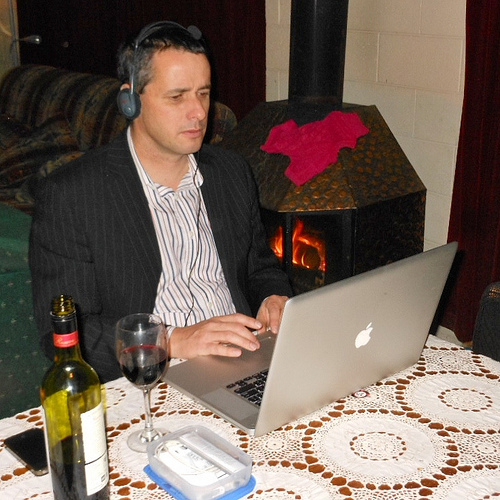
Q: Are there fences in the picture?
A: No, there are no fences.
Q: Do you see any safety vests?
A: No, there are no safety vests.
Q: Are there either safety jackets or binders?
A: No, there are no safety jackets or binders.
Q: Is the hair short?
A: Yes, the hair is short.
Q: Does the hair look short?
A: Yes, the hair is short.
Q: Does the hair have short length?
A: Yes, the hair is short.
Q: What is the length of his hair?
A: The hair is short.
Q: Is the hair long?
A: No, the hair is short.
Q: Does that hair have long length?
A: No, the hair is short.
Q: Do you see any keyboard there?
A: Yes, there is a keyboard.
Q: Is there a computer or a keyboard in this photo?
A: Yes, there is a keyboard.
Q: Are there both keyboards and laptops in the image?
A: Yes, there are both a keyboard and a laptop.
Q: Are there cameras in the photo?
A: No, there are no cameras.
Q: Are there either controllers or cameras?
A: No, there are no cameras or controllers.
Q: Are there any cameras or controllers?
A: No, there are no cameras or controllers.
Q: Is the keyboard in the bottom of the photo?
A: Yes, the keyboard is in the bottom of the image.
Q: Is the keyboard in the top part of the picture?
A: No, the keyboard is in the bottom of the image.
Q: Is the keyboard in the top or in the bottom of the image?
A: The keyboard is in the bottom of the image.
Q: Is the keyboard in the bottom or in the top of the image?
A: The keyboard is in the bottom of the image.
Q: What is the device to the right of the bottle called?
A: The device is a keyboard.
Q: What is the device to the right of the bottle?
A: The device is a keyboard.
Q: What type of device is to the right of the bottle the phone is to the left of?
A: The device is a keyboard.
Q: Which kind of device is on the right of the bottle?
A: The device is a keyboard.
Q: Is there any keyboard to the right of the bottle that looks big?
A: Yes, there is a keyboard to the right of the bottle.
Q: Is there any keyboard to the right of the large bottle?
A: Yes, there is a keyboard to the right of the bottle.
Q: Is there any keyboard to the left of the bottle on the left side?
A: No, the keyboard is to the right of the bottle.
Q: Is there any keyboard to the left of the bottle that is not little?
A: No, the keyboard is to the right of the bottle.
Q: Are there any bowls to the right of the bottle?
A: No, there is a keyboard to the right of the bottle.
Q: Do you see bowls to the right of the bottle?
A: No, there is a keyboard to the right of the bottle.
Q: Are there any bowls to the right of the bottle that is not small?
A: No, there is a keyboard to the right of the bottle.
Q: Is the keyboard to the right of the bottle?
A: Yes, the keyboard is to the right of the bottle.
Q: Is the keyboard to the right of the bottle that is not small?
A: Yes, the keyboard is to the right of the bottle.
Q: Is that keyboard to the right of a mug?
A: No, the keyboard is to the right of the bottle.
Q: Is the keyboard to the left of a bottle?
A: No, the keyboard is to the right of a bottle.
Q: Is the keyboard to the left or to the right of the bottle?
A: The keyboard is to the right of the bottle.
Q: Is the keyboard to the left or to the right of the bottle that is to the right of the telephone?
A: The keyboard is to the right of the bottle.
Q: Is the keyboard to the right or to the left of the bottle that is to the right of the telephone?
A: The keyboard is to the right of the bottle.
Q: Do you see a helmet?
A: No, there are no helmets.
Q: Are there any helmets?
A: No, there are no helmets.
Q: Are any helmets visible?
A: No, there are no helmets.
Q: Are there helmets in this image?
A: No, there are no helmets.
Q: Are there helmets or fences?
A: No, there are no helmets or fences.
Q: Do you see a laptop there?
A: Yes, there is a laptop.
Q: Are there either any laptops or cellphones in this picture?
A: Yes, there is a laptop.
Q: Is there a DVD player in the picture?
A: No, there are no DVD players.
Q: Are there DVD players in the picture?
A: No, there are no DVD players.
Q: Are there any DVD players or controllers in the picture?
A: No, there are no DVD players or controllers.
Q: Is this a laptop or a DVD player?
A: This is a laptop.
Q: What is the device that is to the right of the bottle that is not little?
A: The device is a laptop.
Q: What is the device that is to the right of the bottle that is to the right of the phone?
A: The device is a laptop.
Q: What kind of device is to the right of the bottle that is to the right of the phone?
A: The device is a laptop.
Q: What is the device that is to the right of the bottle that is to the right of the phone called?
A: The device is a laptop.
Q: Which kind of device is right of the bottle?
A: The device is a laptop.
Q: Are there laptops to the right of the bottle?
A: Yes, there is a laptop to the right of the bottle.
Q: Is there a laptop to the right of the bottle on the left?
A: Yes, there is a laptop to the right of the bottle.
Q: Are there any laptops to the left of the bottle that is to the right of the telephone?
A: No, the laptop is to the right of the bottle.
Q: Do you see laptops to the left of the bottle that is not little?
A: No, the laptop is to the right of the bottle.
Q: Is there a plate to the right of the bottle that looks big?
A: No, there is a laptop to the right of the bottle.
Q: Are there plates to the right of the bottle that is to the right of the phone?
A: No, there is a laptop to the right of the bottle.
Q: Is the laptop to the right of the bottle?
A: Yes, the laptop is to the right of the bottle.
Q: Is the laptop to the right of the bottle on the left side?
A: Yes, the laptop is to the right of the bottle.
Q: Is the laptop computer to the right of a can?
A: No, the laptop computer is to the right of the bottle.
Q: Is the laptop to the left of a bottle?
A: No, the laptop is to the right of a bottle.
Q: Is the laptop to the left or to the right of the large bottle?
A: The laptop is to the right of the bottle.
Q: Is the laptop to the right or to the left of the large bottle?
A: The laptop is to the right of the bottle.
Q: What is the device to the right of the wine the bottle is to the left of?
A: The device is a laptop.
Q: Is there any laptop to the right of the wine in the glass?
A: Yes, there is a laptop to the right of the wine.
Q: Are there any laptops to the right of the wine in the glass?
A: Yes, there is a laptop to the right of the wine.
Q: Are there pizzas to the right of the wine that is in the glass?
A: No, there is a laptop to the right of the wine.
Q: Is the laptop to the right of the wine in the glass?
A: Yes, the laptop is to the right of the wine.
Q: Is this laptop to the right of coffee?
A: No, the laptop is to the right of the wine.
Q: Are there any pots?
A: No, there are no pots.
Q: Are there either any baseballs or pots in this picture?
A: No, there are no pots or baseballs.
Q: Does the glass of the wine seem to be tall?
A: Yes, the glass is tall.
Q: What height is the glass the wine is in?
A: The glass is tall.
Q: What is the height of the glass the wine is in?
A: The glass is tall.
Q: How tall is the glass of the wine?
A: The glass is tall.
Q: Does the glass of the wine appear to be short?
A: No, the glass is tall.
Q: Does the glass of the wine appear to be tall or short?
A: The glass is tall.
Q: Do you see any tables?
A: Yes, there is a table.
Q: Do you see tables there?
A: Yes, there is a table.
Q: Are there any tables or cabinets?
A: Yes, there is a table.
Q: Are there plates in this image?
A: No, there are no plates.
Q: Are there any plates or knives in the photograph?
A: No, there are no plates or knives.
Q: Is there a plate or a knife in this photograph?
A: No, there are no plates or knives.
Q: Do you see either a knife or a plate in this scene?
A: No, there are no plates or knives.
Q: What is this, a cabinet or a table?
A: This is a table.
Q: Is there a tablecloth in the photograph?
A: Yes, there is a tablecloth.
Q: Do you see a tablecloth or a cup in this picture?
A: Yes, there is a tablecloth.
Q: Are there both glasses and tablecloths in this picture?
A: Yes, there are both a tablecloth and glasses.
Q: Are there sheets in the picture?
A: No, there are no sheets.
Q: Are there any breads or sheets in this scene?
A: No, there are no sheets or breads.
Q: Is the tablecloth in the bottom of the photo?
A: Yes, the tablecloth is in the bottom of the image.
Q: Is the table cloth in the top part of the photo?
A: No, the table cloth is in the bottom of the image.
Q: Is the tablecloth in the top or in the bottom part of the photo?
A: The tablecloth is in the bottom of the image.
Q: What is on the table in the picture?
A: The table cloth is on the table.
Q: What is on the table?
A: The table cloth is on the table.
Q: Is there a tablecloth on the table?
A: Yes, there is a tablecloth on the table.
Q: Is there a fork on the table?
A: No, there is a tablecloth on the table.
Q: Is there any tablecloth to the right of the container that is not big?
A: Yes, there is a tablecloth to the right of the container.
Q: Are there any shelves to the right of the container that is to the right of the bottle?
A: No, there is a tablecloth to the right of the container.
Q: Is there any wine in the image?
A: Yes, there is wine.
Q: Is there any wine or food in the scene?
A: Yes, there is wine.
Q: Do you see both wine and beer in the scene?
A: No, there is wine but no beer.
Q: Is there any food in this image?
A: No, there is no food.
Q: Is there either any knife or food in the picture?
A: No, there are no food or knives.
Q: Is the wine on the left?
A: Yes, the wine is on the left of the image.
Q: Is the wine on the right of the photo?
A: No, the wine is on the left of the image.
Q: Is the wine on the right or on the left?
A: The wine is on the left of the image.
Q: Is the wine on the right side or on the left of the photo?
A: The wine is on the left of the image.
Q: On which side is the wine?
A: The wine is on the left of the image.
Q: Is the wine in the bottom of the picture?
A: Yes, the wine is in the bottom of the image.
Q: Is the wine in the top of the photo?
A: No, the wine is in the bottom of the image.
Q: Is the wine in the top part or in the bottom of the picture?
A: The wine is in the bottom of the image.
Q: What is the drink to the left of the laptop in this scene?
A: The drink is wine.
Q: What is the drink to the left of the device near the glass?
A: The drink is wine.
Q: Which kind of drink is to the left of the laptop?
A: The drink is wine.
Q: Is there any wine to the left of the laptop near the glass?
A: Yes, there is wine to the left of the laptop.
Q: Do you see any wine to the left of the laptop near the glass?
A: Yes, there is wine to the left of the laptop.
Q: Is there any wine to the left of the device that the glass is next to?
A: Yes, there is wine to the left of the laptop.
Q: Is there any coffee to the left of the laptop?
A: No, there is wine to the left of the laptop.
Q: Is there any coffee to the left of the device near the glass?
A: No, there is wine to the left of the laptop.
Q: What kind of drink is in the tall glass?
A: The drink is wine.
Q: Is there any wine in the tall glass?
A: Yes, there is wine in the glass.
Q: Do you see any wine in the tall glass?
A: Yes, there is wine in the glass.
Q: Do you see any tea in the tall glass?
A: No, there is wine in the glass.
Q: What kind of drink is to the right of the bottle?
A: The drink is wine.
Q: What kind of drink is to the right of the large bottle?
A: The drink is wine.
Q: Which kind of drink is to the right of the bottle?
A: The drink is wine.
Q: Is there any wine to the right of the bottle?
A: Yes, there is wine to the right of the bottle.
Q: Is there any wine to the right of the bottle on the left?
A: Yes, there is wine to the right of the bottle.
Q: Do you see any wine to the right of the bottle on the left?
A: Yes, there is wine to the right of the bottle.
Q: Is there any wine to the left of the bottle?
A: No, the wine is to the right of the bottle.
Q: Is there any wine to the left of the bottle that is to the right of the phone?
A: No, the wine is to the right of the bottle.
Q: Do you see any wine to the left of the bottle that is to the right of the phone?
A: No, the wine is to the right of the bottle.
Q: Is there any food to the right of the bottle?
A: No, there is wine to the right of the bottle.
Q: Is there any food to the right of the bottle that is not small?
A: No, there is wine to the right of the bottle.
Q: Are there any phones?
A: Yes, there is a phone.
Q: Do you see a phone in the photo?
A: Yes, there is a phone.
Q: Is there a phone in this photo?
A: Yes, there is a phone.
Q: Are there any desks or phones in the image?
A: Yes, there is a phone.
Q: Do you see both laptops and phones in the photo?
A: Yes, there are both a phone and a laptop.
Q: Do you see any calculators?
A: No, there are no calculators.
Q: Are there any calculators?
A: No, there are no calculators.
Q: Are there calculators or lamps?
A: No, there are no calculators or lamps.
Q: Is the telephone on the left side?
A: Yes, the telephone is on the left of the image.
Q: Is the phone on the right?
A: No, the phone is on the left of the image.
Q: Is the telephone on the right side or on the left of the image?
A: The telephone is on the left of the image.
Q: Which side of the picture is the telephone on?
A: The telephone is on the left of the image.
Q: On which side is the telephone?
A: The telephone is on the left of the image.